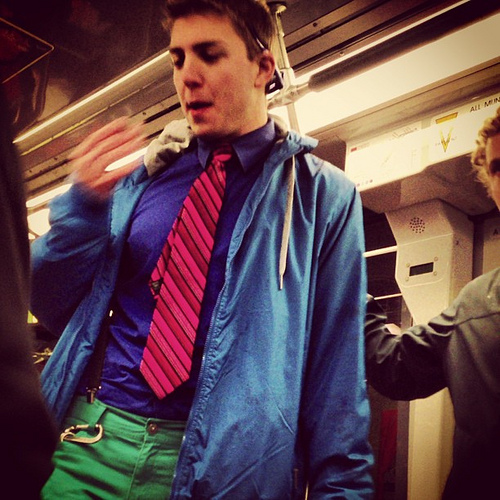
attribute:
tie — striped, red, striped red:
[137, 141, 232, 399]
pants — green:
[37, 390, 188, 500]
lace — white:
[275, 154, 297, 294]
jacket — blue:
[26, 133, 374, 500]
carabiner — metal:
[63, 422, 103, 443]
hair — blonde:
[478, 107, 500, 210]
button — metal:
[146, 421, 159, 435]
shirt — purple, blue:
[77, 117, 277, 422]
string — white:
[277, 146, 296, 288]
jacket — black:
[365, 266, 499, 500]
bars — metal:
[5, 4, 303, 200]